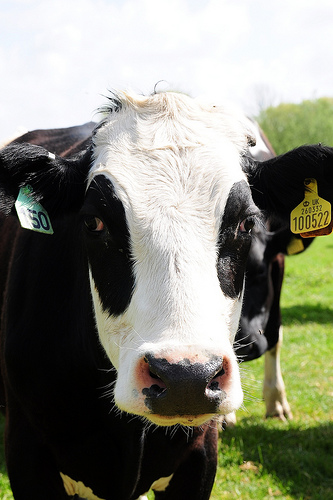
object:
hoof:
[262, 388, 294, 424]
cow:
[232, 253, 292, 420]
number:
[293, 202, 332, 228]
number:
[16, 203, 53, 231]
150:
[18, 205, 53, 231]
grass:
[206, 235, 333, 500]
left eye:
[232, 216, 256, 237]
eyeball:
[234, 212, 256, 236]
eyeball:
[82, 214, 106, 230]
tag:
[9, 176, 61, 234]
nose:
[131, 348, 231, 417]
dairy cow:
[0, 89, 331, 499]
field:
[261, 333, 332, 497]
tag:
[286, 186, 330, 237]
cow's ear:
[251, 141, 333, 241]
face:
[56, 95, 288, 428]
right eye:
[79, 214, 104, 230]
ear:
[2, 137, 80, 246]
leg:
[258, 319, 297, 426]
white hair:
[84, 88, 249, 427]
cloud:
[0, 3, 218, 99]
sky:
[0, 0, 330, 105]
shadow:
[219, 416, 331, 498]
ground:
[0, 231, 331, 498]